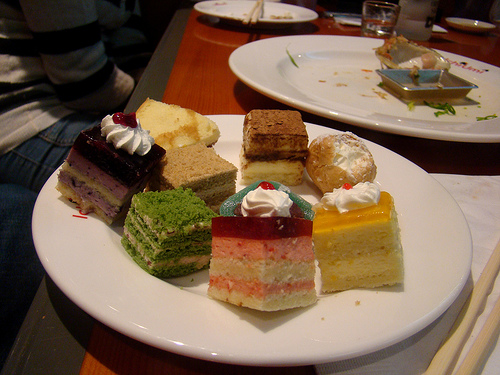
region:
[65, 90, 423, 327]
several square pieces of cake on the plate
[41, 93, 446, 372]
a round white plate filled with cake samples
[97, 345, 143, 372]
brown wood surface of the table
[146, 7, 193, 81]
grey stripe around the edge of the table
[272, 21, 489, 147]
a dirty white plate on the table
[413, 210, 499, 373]
two white wood sticks on the table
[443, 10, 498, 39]
a small white saucer on the table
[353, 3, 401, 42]
an empty clear glass on the table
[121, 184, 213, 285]
a square piece of green and white cake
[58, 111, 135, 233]
a square piece of purple and white tape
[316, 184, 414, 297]
Yellow cake with whip cream.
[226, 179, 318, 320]
Red piece of cake with whip cream.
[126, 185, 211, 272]
Green and white piece of cake.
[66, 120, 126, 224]
Purple piece of cake with whip cream.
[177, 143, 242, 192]
Tan piece of cake on a plate.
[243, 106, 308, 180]
Brown piece of cake on a plate.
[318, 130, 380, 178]
Small pastry with creme in the inside.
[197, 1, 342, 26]
Empty plate with chopsticks on it.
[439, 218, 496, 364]
Pair of chopsticks on the table.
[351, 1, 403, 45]
Empty glass on top of a table.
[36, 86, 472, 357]
petit cakes on a plate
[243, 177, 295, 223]
whipped cream on a cake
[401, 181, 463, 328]
white plate under cakes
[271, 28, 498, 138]
food on a plate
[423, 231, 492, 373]
chopsticks on a table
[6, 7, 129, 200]
person sitting at a table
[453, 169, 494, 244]
napkin by a plate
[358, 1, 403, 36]
glass on a table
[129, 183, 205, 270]
green layered cake on plate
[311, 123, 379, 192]
cream puff on a plate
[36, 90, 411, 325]
white plate filled with pettifors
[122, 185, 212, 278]
green pettifor on the plate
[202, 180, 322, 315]
pettifor with white and pink layers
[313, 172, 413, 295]
yellow pettifor with white icing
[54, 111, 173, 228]
purple pasty on the plate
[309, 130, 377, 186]
circular cream puff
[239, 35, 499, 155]
empty white plate with metal cup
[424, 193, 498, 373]
two wooden chopsticks on a napkin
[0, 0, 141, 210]
person sitting at the table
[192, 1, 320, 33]
empty plates with chopsticks on it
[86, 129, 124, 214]
Purple dessert on plate.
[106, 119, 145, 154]
Whip cream on top of purple dessert.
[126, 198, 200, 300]
Green dessert on white plate.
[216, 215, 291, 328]
White, pink, and red dessert on plate.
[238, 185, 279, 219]
Whip cream on top of dessert.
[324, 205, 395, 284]
Yellow dessert on plate.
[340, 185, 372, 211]
Whip cream on top of dessert.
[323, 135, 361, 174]
Brown and white dessert on top of plate.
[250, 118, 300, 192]
Brown and white dessert on top of plate.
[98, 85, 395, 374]
Plate is white and round.